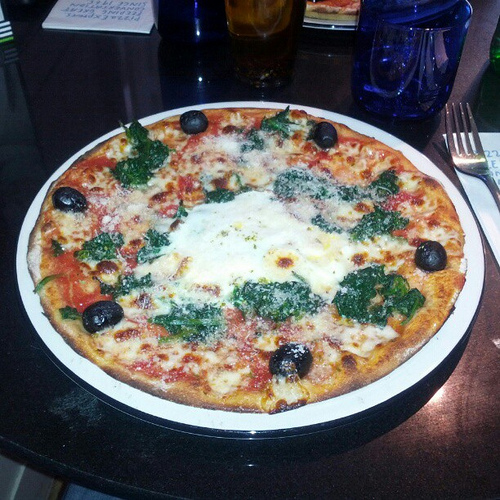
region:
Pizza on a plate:
[26, 104, 468, 416]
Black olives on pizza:
[56, 110, 445, 373]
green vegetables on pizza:
[35, 106, 427, 339]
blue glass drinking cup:
[354, 0, 473, 120]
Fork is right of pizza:
[445, 98, 499, 226]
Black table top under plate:
[0, 0, 499, 497]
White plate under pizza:
[13, 98, 487, 438]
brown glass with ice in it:
[223, 1, 306, 92]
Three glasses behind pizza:
[151, 3, 472, 121]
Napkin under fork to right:
[445, 128, 498, 268]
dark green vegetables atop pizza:
[333, 262, 428, 338]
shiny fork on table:
[442, 94, 499, 224]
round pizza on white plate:
[15, 93, 484, 436]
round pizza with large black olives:
[12, 91, 480, 445]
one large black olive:
[174, 110, 209, 137]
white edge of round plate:
[123, 389, 383, 434]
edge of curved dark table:
[16, 408, 152, 496]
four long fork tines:
[441, 98, 474, 148]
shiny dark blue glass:
[351, 18, 451, 128]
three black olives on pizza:
[79, 238, 449, 380]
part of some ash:
[260, 205, 322, 260]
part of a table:
[391, 436, 442, 485]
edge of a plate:
[231, 409, 288, 449]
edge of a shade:
[381, 403, 419, 430]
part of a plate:
[272, 411, 317, 446]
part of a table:
[411, 405, 463, 476]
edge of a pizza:
[329, 370, 350, 397]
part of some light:
[428, 386, 449, 409]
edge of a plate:
[287, 419, 330, 444]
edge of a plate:
[58, 467, 88, 494]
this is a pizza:
[74, 150, 389, 332]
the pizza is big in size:
[71, 162, 413, 332]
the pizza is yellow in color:
[421, 197, 451, 234]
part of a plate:
[420, 350, 437, 367]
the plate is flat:
[417, 352, 437, 372]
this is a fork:
[439, 102, 488, 167]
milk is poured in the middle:
[175, 183, 310, 283]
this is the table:
[423, 387, 490, 478]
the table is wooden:
[412, 399, 471, 476]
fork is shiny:
[454, 115, 484, 168]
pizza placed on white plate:
[27, 123, 471, 392]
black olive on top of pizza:
[44, 167, 150, 272]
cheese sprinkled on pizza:
[78, 144, 161, 232]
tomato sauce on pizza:
[131, 326, 290, 416]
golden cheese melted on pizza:
[137, 337, 261, 387]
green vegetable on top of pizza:
[225, 278, 353, 349]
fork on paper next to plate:
[394, 63, 490, 350]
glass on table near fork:
[319, 16, 498, 152]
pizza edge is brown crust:
[308, 319, 419, 386]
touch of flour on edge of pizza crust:
[369, 305, 446, 381]